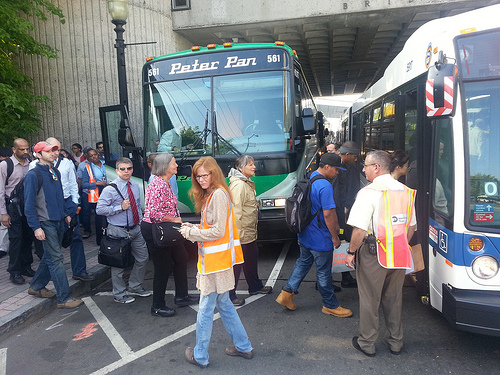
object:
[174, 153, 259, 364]
lady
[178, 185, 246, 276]
jacket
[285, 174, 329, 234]
backpack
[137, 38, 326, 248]
bus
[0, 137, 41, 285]
man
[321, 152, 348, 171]
hat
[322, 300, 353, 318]
boots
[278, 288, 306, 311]
boot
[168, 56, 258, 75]
name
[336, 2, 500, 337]
blue/white bus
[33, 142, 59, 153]
baseball cap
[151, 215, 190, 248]
bag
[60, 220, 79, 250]
bag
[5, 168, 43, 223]
bag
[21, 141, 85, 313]
everyone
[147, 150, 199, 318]
lady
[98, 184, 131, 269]
briefcase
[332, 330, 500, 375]
ground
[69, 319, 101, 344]
red paint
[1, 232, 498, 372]
street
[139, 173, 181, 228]
floral shirt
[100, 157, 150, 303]
man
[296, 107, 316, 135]
mirror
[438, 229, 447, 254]
handicap sticker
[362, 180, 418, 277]
red vest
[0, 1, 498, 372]
bus station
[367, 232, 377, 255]
walkie talkie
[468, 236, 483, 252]
turn signal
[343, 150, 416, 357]
man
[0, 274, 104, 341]
curb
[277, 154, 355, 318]
man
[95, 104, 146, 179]
door